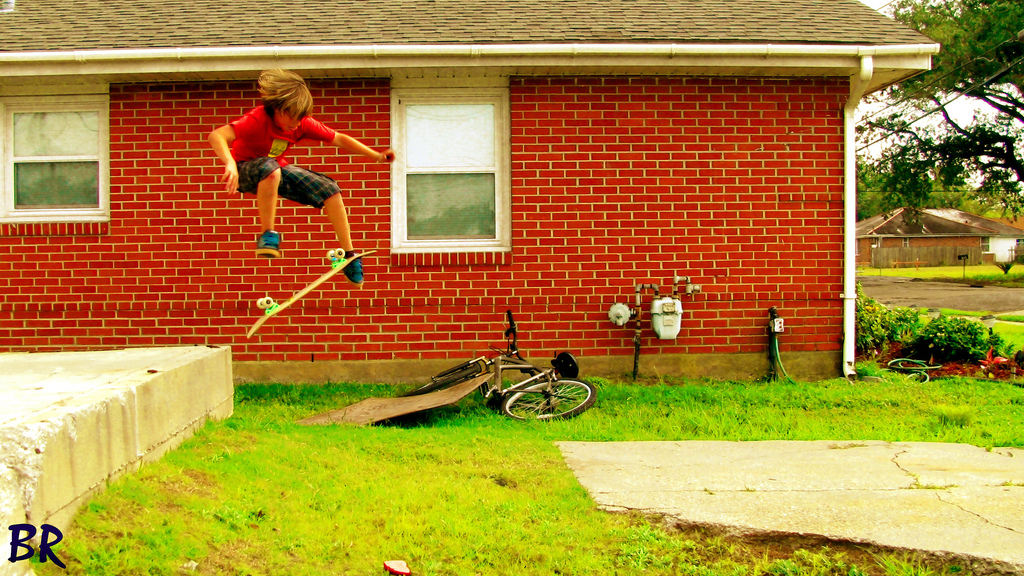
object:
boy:
[208, 67, 395, 287]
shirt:
[224, 105, 336, 167]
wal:
[0, 74, 851, 362]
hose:
[773, 318, 943, 385]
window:
[397, 96, 500, 243]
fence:
[872, 246, 982, 269]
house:
[856, 207, 1024, 268]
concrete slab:
[0, 345, 235, 576]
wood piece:
[292, 372, 497, 425]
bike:
[407, 309, 597, 422]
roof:
[0, 0, 937, 51]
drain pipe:
[0, 44, 941, 62]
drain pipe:
[843, 55, 874, 381]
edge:
[593, 509, 1024, 576]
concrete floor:
[552, 440, 1023, 576]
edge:
[0, 346, 231, 492]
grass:
[900, 471, 961, 489]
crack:
[887, 442, 1024, 534]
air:
[0, 0, 1024, 576]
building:
[0, 0, 941, 386]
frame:
[390, 88, 512, 254]